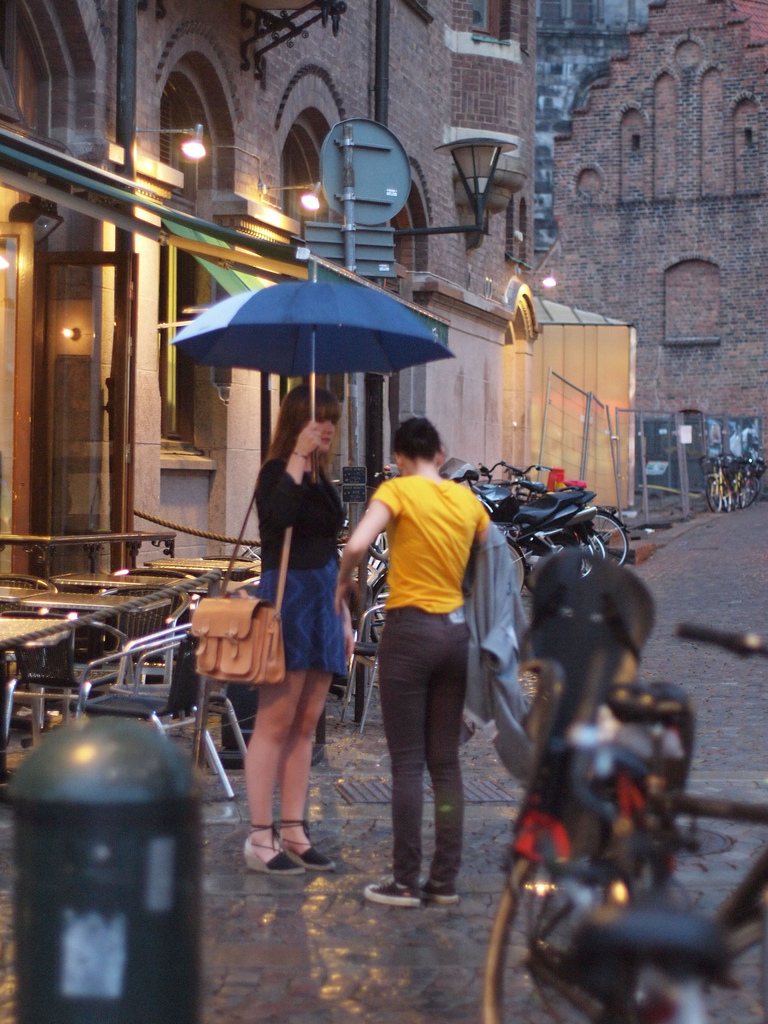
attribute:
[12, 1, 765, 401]
buildings — old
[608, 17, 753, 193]
buildings — red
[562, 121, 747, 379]
buildings — brick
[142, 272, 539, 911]
people — standing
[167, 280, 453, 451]
umbrella — blue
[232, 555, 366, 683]
skirt — blue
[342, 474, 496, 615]
shirt — yellow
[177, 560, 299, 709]
bag — tan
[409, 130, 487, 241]
pole — black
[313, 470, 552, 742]
shirt — yellow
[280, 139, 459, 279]
post — gray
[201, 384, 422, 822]
dress — blue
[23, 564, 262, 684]
rope — brown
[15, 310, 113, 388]
wall — brick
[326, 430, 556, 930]
shoes — black and white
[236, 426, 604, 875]
person — black and white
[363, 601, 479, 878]
pants — brown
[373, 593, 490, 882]
pants — brown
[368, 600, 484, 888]
pants — brown